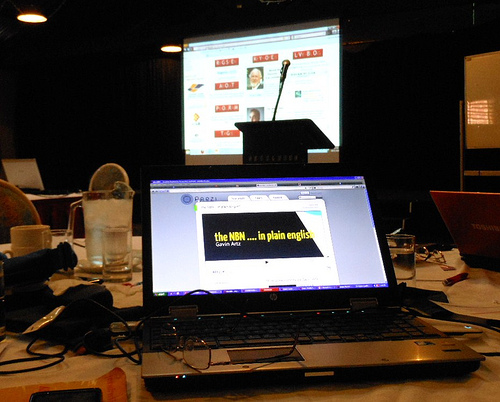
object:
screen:
[150, 176, 387, 291]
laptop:
[135, 158, 486, 390]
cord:
[3, 296, 145, 377]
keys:
[150, 312, 430, 347]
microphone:
[277, 59, 293, 88]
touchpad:
[225, 343, 304, 364]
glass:
[101, 223, 132, 281]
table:
[1, 233, 499, 401]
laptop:
[430, 188, 498, 272]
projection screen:
[178, 17, 345, 169]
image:
[246, 66, 263, 90]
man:
[247, 108, 263, 122]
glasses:
[157, 320, 305, 370]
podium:
[235, 117, 336, 162]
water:
[391, 249, 415, 279]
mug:
[11, 222, 49, 253]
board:
[462, 48, 500, 149]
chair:
[0, 180, 41, 241]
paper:
[418, 265, 499, 310]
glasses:
[416, 244, 449, 268]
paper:
[413, 250, 484, 282]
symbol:
[212, 57, 242, 67]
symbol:
[214, 80, 238, 91]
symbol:
[211, 101, 240, 112]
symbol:
[214, 128, 241, 138]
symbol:
[251, 51, 280, 62]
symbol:
[293, 47, 325, 61]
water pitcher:
[63, 182, 136, 268]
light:
[17, 4, 50, 26]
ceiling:
[2, 2, 472, 68]